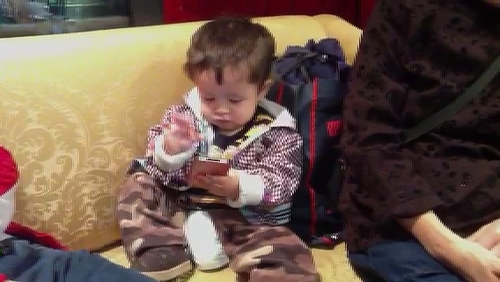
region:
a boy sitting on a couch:
[119, 8, 421, 278]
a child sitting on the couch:
[57, 1, 357, 278]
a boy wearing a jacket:
[144, 31, 328, 266]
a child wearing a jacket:
[99, 31, 354, 278]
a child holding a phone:
[157, 45, 292, 275]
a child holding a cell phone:
[141, 31, 312, 273]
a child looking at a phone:
[114, 11, 300, 278]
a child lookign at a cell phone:
[139, 36, 290, 279]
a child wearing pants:
[87, 34, 290, 274]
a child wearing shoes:
[92, 50, 314, 277]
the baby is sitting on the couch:
[103, 17, 315, 273]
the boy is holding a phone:
[104, 17, 308, 222]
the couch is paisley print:
[18, 47, 128, 249]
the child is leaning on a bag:
[180, 14, 345, 275]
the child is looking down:
[148, 14, 259, 149]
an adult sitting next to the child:
[290, 2, 484, 253]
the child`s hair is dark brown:
[165, 12, 270, 122]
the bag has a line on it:
[284, 49, 334, 249]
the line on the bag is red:
[290, 41, 344, 257]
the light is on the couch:
[8, 26, 159, 76]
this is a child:
[16, 31, 418, 253]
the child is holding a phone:
[159, 24, 324, 280]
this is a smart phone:
[181, 146, 268, 217]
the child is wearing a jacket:
[141, 88, 350, 279]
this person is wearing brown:
[349, 16, 494, 163]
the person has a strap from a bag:
[373, 47, 489, 167]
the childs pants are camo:
[111, 184, 207, 254]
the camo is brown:
[116, 187, 187, 248]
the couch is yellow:
[16, 76, 148, 219]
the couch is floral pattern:
[26, 93, 92, 177]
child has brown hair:
[165, 23, 262, 90]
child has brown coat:
[146, 84, 278, 204]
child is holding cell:
[195, 129, 227, 186]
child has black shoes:
[141, 221, 208, 280]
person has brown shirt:
[365, 30, 484, 239]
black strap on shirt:
[375, 32, 495, 152]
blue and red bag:
[280, 27, 357, 229]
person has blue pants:
[353, 220, 465, 277]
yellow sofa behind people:
[14, 55, 113, 187]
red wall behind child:
[139, 0, 249, 34]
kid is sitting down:
[115, 18, 320, 280]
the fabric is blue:
[0, 238, 157, 280]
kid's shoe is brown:
[125, 245, 191, 280]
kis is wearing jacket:
[147, 87, 299, 205]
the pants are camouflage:
[117, 169, 318, 280]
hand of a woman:
[439, 233, 499, 280]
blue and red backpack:
[270, 32, 352, 244]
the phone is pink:
[188, 154, 226, 190]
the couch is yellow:
[0, 12, 361, 280]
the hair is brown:
[185, 16, 275, 94]